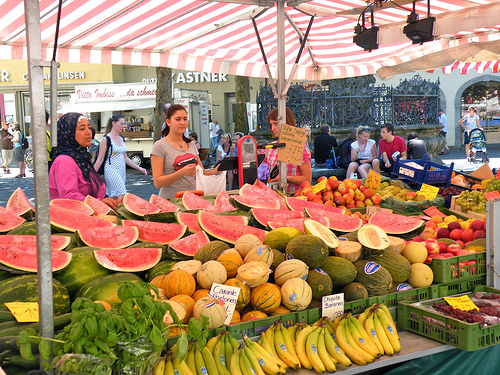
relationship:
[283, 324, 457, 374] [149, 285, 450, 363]
table holds bananas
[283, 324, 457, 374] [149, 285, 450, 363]
table displays bananas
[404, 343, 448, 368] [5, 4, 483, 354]
table creates a fruit stand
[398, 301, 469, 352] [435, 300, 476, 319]
edge secures merchandise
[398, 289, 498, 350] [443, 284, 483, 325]
crate secures merchandise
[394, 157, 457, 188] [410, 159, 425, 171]
crate totes fruit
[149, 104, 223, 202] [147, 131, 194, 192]
consumers wearing shirt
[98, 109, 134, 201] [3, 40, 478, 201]
woman walking through town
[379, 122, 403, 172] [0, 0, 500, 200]
man visitting town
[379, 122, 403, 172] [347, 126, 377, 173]
man visitting woman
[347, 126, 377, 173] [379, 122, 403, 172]
woman visitting man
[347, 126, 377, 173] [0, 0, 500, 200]
woman visitting town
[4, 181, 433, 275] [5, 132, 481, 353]
watermelon decorates fruit stand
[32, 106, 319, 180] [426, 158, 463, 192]
consumers walk along ground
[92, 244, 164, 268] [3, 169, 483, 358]
green watermelon displaying in fruit stand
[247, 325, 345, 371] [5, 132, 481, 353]
yellow bananas border fruit stand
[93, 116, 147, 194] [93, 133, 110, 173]
woman with backpack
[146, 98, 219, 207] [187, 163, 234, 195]
woman holding bag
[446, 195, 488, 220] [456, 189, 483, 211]
produce box containing grapes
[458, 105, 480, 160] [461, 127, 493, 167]
woman pushing stroller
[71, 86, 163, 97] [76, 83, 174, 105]
red lettering on white sign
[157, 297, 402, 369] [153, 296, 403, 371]
row of bananas